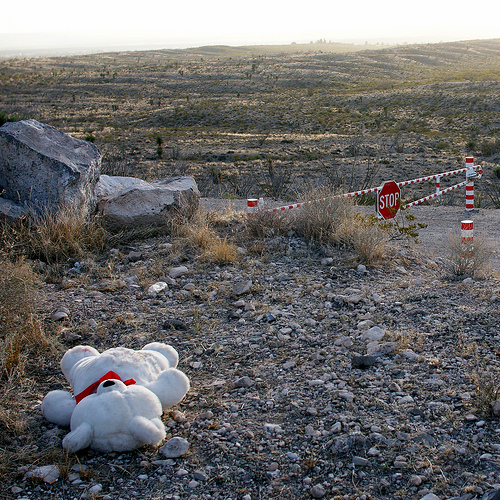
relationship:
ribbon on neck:
[75, 374, 145, 399] [75, 371, 156, 405]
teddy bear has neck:
[36, 340, 193, 462] [75, 371, 156, 405]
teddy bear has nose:
[36, 340, 193, 462] [98, 378, 118, 390]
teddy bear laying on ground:
[36, 340, 193, 462] [3, 226, 498, 499]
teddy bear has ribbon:
[36, 340, 193, 462] [75, 374, 145, 399]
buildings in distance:
[295, 33, 396, 51] [5, 3, 499, 69]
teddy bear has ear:
[36, 340, 193, 462] [127, 417, 182, 447]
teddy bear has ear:
[36, 340, 193, 462] [66, 427, 95, 457]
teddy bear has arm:
[36, 340, 193, 462] [150, 365, 194, 420]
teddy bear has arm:
[36, 340, 193, 462] [40, 389, 83, 431]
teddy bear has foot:
[36, 340, 193, 462] [142, 340, 181, 369]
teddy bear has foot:
[36, 340, 193, 462] [55, 342, 97, 370]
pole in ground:
[456, 158, 481, 209] [3, 226, 498, 499]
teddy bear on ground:
[36, 340, 193, 462] [3, 226, 498, 499]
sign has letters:
[376, 181, 405, 220] [378, 190, 402, 211]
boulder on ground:
[3, 115, 211, 247] [3, 226, 498, 499]